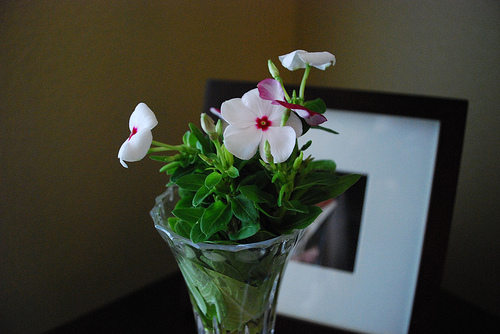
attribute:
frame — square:
[198, 76, 472, 332]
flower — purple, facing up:
[105, 40, 338, 210]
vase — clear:
[144, 183, 333, 333]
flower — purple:
[113, 100, 202, 184]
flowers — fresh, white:
[109, 45, 359, 212]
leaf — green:
[187, 171, 223, 207]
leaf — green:
[196, 202, 232, 241]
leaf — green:
[182, 128, 200, 150]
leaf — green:
[301, 163, 362, 204]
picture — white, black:
[313, 75, 466, 333]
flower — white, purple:
[214, 84, 303, 165]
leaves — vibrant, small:
[167, 161, 270, 233]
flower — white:
[277, 43, 340, 75]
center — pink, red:
[253, 116, 272, 133]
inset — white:
[318, 115, 433, 326]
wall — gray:
[3, 6, 118, 301]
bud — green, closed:
[196, 109, 220, 139]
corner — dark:
[235, 0, 329, 48]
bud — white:
[262, 139, 279, 165]